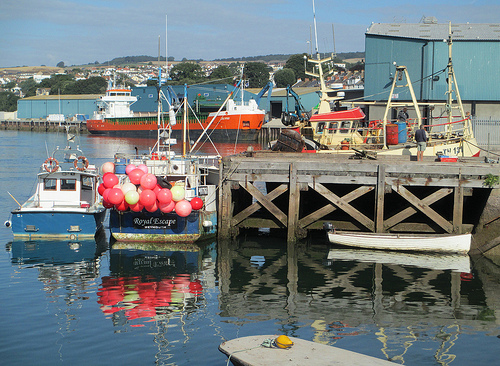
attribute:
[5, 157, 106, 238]
boat — blue, white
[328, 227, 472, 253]
boat — white, small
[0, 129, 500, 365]
water — calm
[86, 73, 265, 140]
boat — white, orange, large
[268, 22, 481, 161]
boat — red, white, large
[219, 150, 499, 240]
pier — wooden, grey, old, brown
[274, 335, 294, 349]
bouy — yellow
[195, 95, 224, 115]
engine — green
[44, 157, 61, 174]
innertube — orange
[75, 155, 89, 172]
innertube — orange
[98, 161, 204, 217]
balloons — pink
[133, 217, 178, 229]
name — white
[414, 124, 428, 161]
person — standing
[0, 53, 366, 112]
trees — in distane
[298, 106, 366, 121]
roof — red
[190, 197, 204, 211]
balloon — red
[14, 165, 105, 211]
top — white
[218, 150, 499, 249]
dock — brown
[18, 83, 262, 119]
building — blue